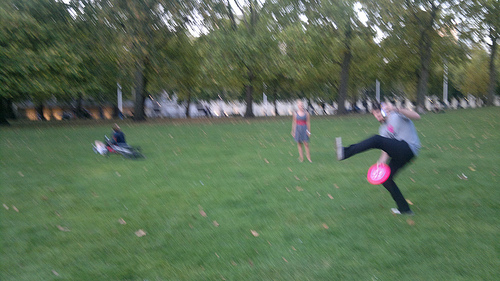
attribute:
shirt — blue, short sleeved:
[377, 111, 438, 151]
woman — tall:
[264, 80, 321, 172]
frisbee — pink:
[324, 142, 448, 226]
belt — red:
[296, 117, 307, 124]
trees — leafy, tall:
[30, 15, 499, 123]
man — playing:
[326, 92, 433, 222]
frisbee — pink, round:
[360, 159, 394, 186]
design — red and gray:
[386, 123, 400, 140]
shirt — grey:
[376, 112, 421, 155]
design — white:
[372, 167, 385, 181]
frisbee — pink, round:
[364, 162, 390, 184]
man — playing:
[335, 96, 421, 214]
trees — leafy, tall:
[110, 54, 445, 133]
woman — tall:
[285, 96, 318, 160]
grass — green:
[0, 105, 500, 279]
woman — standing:
[292, 97, 311, 164]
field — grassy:
[1, 102, 497, 279]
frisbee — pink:
[362, 162, 392, 183]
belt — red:
[293, 116, 310, 126]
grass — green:
[204, 169, 375, 274]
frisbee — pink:
[366, 162, 391, 184]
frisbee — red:
[358, 166, 392, 188]